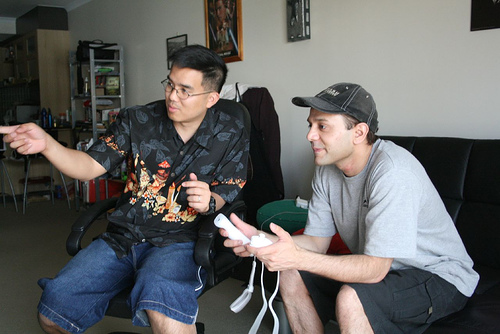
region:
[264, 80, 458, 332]
a man sitting on a couch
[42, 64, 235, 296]
a man sitting in a desk chair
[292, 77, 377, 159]
a man wearing a hat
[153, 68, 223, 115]
a man wearing glasses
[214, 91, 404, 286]
a man holding a gaming controller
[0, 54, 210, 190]
a man pointing his finger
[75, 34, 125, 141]
a metal shelf in a corner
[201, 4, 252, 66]
a picture hanging on a wall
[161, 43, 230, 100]
a man with black hair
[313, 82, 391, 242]
a man wearing a grey shirt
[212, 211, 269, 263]
white game controller in hand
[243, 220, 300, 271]
white game controller in hand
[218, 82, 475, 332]
man sitting on green sofa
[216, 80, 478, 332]
man wearing baseball cap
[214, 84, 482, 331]
man wearing gray t-shirt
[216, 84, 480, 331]
man wearing black shorts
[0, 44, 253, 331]
man wearing jean shorts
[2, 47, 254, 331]
man sitting on desk chair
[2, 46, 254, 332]
man wearing black rim glasses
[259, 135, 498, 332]
green sofa against white wall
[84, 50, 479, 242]
two men are sitting down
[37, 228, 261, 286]
the man is wearing jean shirts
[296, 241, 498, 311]
the man is wearing dark shorts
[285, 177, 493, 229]
the man is wearing a gray shirt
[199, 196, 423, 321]
the man is holding wii remotes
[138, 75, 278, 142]
the man is wearing glasses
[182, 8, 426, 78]
pictures are on the wall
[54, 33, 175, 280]
the bookshelf is in the corner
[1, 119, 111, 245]
a table is by the bookshelf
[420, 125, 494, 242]
the couch is black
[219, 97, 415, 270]
this is a man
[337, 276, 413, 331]
this is a pair of shorts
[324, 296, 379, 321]
this is a leg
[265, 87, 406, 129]
this is a hat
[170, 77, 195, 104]
this is a pair of glasses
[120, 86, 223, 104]
the glasses have no rims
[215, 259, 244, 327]
this is a strap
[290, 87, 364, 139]
the cap is black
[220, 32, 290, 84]
this is a painting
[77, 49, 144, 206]
this is a shelf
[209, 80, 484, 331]
Man wearing a black hat sitting on couch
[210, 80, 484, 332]
Man wearing a gray shirt and playing wii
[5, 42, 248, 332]
Man with glasses sitting in chair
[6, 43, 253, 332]
Man wearing black shirt pointing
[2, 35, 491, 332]
Two men playing a video game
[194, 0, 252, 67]
Picture in a frame hanging on wall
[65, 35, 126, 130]
Gray shelf in room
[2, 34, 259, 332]
Man with black hair, wearing jean shorts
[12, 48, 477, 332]
Two men wearing shorts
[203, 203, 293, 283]
White wii remote